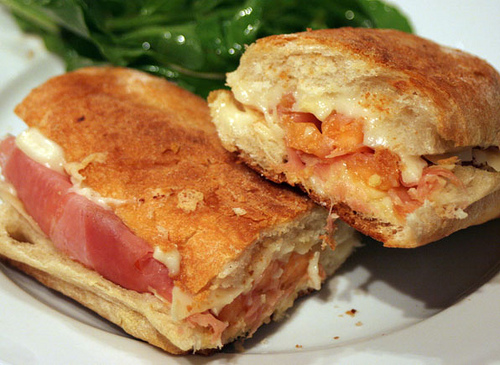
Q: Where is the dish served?
A: In a restaurant.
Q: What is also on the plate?
A: Green garnish.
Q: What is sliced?
A: The sandwich.